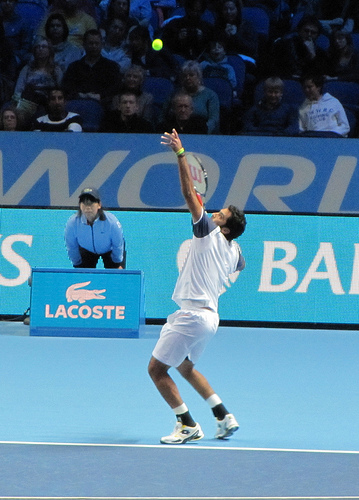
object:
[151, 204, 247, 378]
outfit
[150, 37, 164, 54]
ball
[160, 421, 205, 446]
shoe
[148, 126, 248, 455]
man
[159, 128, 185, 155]
hand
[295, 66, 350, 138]
spectators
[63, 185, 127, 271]
woman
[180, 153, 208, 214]
racket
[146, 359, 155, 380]
knees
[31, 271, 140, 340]
sign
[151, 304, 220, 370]
shorts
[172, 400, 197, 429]
socks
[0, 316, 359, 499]
court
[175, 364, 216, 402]
calves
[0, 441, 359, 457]
line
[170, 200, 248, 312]
shirt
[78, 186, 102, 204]
cap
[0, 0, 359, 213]
stand